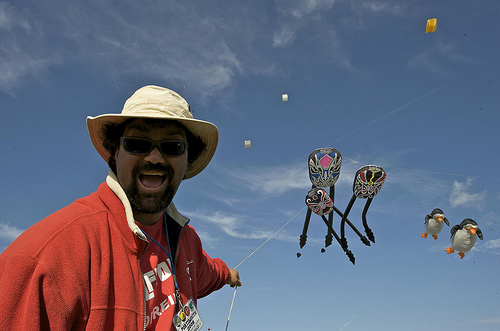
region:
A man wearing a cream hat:
[72, 69, 226, 226]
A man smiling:
[84, 66, 227, 231]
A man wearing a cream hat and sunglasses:
[55, 66, 232, 226]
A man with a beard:
[114, 160, 182, 217]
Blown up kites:
[255, 120, 400, 287]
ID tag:
[157, 294, 217, 330]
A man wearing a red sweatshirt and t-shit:
[5, 75, 255, 330]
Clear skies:
[107, 11, 374, 77]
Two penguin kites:
[417, 178, 488, 287]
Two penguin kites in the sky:
[411, 189, 488, 278]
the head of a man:
[112, 73, 230, 218]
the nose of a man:
[136, 141, 172, 166]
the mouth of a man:
[130, 158, 189, 199]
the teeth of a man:
[121, 163, 184, 190]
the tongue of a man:
[125, 165, 170, 207]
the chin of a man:
[106, 183, 200, 236]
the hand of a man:
[222, 245, 264, 302]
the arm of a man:
[178, 198, 274, 308]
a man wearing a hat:
[51, 47, 237, 184]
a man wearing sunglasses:
[100, 105, 232, 218]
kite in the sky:
[353, 161, 395, 235]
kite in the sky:
[304, 145, 345, 199]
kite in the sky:
[448, 216, 491, 266]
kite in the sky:
[409, 208, 452, 245]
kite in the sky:
[303, 190, 349, 244]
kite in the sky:
[271, 90, 306, 138]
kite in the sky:
[236, 133, 276, 170]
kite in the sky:
[407, 3, 440, 58]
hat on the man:
[93, 78, 220, 174]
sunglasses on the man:
[123, 132, 179, 160]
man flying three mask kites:
[5, 88, 387, 328]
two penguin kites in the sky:
[421, 207, 481, 256]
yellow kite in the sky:
[424, 15, 439, 35]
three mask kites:
[297, 145, 385, 262]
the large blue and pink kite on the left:
[295, 145, 337, 255]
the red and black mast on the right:
[337, 157, 382, 247]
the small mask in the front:
[305, 188, 371, 265]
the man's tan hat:
[88, 85, 217, 179]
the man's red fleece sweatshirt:
[3, 183, 230, 330]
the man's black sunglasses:
[119, 137, 186, 158]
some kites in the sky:
[240, 62, 499, 309]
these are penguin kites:
[406, 177, 483, 281]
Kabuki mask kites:
[283, 129, 417, 321]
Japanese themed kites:
[276, 120, 415, 298]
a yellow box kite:
[398, 7, 460, 59]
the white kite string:
[221, 191, 308, 329]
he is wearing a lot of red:
[2, 37, 265, 330]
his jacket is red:
[1, 54, 288, 328]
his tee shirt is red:
[113, 194, 197, 324]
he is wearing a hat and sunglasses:
[61, 66, 254, 257]